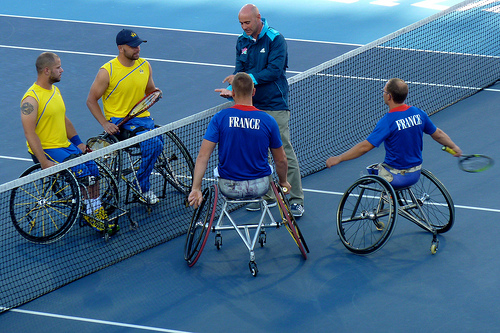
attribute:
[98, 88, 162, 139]
raquette — red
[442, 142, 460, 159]
handle — yellow 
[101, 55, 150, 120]
shirt — yellow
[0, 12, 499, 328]
court — for tennis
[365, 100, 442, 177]
shirt — blue 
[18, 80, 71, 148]
shirt — yellow 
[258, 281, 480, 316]
ground — blue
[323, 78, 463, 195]
man — physically challeged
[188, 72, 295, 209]
man — physically challeged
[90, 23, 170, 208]
man — physically challeged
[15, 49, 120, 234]
man — physically challeged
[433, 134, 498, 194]
racket — for tennis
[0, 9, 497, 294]
net — black , white 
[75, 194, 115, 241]
sneaker — yellow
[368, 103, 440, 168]
shirt — blue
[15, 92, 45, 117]
tattoo — black 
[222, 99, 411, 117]
trim — red